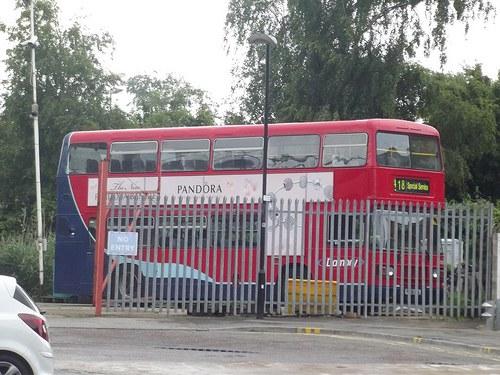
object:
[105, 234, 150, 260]
gray sign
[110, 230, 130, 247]
white letters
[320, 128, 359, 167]
window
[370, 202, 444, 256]
window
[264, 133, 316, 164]
glass window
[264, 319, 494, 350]
sidewalk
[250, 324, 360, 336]
curb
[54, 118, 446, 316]
bus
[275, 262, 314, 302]
tire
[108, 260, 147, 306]
tire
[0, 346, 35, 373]
tire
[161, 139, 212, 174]
window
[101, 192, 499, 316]
fence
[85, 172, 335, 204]
sign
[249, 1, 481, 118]
trees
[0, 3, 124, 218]
trees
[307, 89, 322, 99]
leaves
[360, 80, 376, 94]
leaves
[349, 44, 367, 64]
leaves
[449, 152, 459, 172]
leaves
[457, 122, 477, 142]
leaves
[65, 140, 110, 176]
side window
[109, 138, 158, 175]
side window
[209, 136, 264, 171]
side window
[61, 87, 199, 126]
leaves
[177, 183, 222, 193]
black letters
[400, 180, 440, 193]
letters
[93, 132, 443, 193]
decks